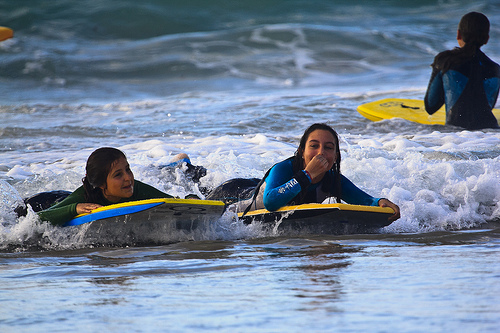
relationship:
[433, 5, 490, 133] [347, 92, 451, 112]
person next to surfboard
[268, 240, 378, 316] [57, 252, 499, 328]
reflection on water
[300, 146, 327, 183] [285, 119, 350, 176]
lifted hand in front of face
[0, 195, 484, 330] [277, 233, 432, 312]
reflection on water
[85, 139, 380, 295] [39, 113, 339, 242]
these are two ladies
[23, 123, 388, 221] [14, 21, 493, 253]
ladies are sea surfing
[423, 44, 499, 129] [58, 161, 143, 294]
costume black in color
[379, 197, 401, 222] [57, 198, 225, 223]
hand on edge of surfboard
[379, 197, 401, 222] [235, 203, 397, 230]
hand on edge of surfboard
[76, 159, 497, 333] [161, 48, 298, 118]
body of water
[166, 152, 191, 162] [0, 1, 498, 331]
foot sticking out of water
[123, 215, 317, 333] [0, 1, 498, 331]
part of a water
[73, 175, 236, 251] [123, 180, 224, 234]
part of a board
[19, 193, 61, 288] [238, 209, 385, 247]
part of a splash